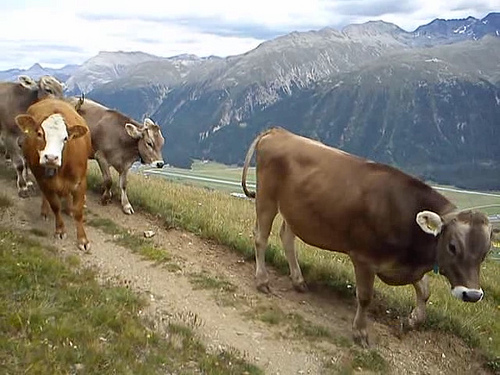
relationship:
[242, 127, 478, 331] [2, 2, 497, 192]
cow on mountain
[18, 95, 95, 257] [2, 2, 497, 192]
cow on mountain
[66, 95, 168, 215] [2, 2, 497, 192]
cow on mountain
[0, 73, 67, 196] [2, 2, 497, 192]
cow on mountain